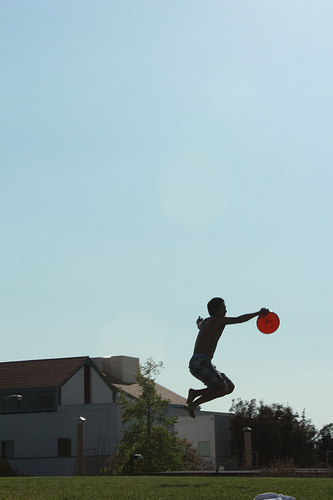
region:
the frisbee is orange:
[251, 293, 292, 335]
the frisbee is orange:
[242, 304, 282, 352]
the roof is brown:
[11, 360, 80, 392]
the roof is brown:
[4, 360, 53, 381]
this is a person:
[175, 282, 240, 420]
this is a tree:
[91, 351, 207, 477]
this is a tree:
[233, 386, 276, 469]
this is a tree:
[273, 404, 319, 475]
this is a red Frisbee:
[259, 302, 285, 344]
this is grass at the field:
[28, 467, 80, 498]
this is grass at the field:
[112, 477, 137, 491]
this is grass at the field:
[180, 467, 222, 497]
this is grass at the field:
[235, 471, 297, 497]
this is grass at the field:
[152, 472, 185, 497]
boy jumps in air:
[186, 283, 247, 395]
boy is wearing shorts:
[177, 352, 231, 390]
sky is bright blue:
[94, 105, 166, 221]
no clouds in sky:
[72, 85, 164, 219]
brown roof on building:
[14, 360, 86, 407]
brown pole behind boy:
[224, 423, 263, 463]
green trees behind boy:
[117, 375, 298, 484]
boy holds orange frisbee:
[252, 319, 290, 344]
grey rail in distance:
[167, 464, 320, 485]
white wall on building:
[5, 398, 108, 451]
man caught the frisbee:
[176, 260, 296, 436]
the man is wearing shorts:
[186, 352, 234, 404]